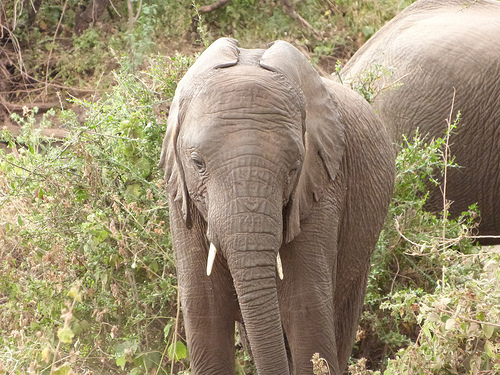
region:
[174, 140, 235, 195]
the eye of a elephant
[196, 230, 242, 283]
the tusk on a elephant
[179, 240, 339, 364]
the trunk of a elephant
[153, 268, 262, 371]
the leg of a elephant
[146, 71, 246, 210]
the ear of a elephant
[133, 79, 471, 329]
a grey baby elephant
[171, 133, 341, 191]
the eyes of a grey elephant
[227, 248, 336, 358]
the grey trunk of a elephant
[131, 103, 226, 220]
the grey ear of a elephant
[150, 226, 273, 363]
the grey leg of a elephant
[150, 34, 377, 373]
baby elephant looking sad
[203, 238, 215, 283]
baby elephant tusk left side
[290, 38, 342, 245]
baby elephant ear on right side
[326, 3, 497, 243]
large elephant in back of baby elephant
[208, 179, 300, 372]
baby elephant trunk and tusk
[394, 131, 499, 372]
green bush on side of elephant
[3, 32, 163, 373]
green grass behind elephant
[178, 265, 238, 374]
leg of baby elephant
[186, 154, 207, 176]
eye of the baby elephant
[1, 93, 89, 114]
branch in back of elepant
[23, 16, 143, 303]
these are some bushes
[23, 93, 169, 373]
the bushes are big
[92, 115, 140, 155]
these are some leaves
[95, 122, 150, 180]
the leaves are green in color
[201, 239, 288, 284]
these are some tusks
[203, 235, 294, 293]
the tusks are small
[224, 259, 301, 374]
this is a trunk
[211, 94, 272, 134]
the skin is wrinkled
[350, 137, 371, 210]
the skin is grey in color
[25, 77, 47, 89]
the twigs are grey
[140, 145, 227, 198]
the eye on a elephant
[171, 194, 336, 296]
the tusk on a elephant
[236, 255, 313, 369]
the trunk on a elephant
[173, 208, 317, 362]
the leg of a elephant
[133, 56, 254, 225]
the ear on a elephant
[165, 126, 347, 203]
the eyes on a grey elephant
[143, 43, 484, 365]
a baby grey elephant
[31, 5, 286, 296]
a wooded area near a elephant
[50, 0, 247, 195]
green leaves on a bush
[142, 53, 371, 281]
the head of a elephant